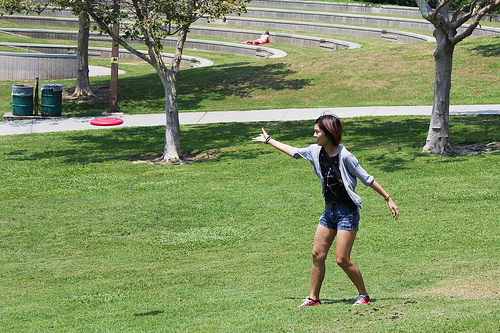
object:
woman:
[253, 115, 401, 307]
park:
[0, 1, 497, 332]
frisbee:
[90, 117, 123, 125]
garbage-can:
[11, 85, 35, 118]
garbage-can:
[42, 83, 63, 118]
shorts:
[319, 199, 359, 231]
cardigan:
[292, 144, 374, 208]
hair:
[318, 115, 343, 145]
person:
[246, 32, 271, 46]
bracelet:
[265, 135, 273, 144]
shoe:
[299, 297, 322, 307]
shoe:
[353, 295, 369, 306]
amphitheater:
[2, 1, 498, 82]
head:
[313, 115, 343, 148]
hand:
[252, 128, 269, 142]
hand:
[387, 199, 399, 220]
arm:
[350, 156, 390, 200]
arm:
[270, 139, 314, 159]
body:
[304, 114, 362, 297]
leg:
[337, 224, 365, 295]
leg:
[310, 223, 336, 299]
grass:
[2, 115, 498, 331]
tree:
[67, 1, 249, 163]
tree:
[415, 1, 498, 154]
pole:
[109, 0, 119, 112]